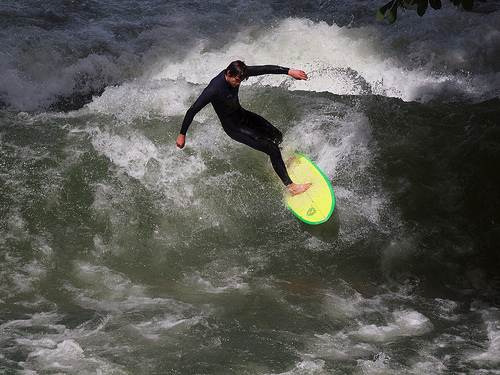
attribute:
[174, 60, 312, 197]
man — balancing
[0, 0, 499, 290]
waves — black, riding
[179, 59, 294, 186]
wet suit — black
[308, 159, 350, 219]
stripe — green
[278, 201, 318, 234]
stripe — green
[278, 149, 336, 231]
board — side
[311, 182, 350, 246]
stripe — green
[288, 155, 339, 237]
board — side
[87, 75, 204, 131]
cap — frothy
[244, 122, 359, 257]
board — side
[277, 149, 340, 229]
board — side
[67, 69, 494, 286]
waves — vicous, crashing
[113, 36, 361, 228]
man — shoeless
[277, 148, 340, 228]
stripe — green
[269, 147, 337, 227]
board — side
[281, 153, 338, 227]
stripe — green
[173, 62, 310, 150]
arms — outstrechted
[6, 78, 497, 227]
waves — foamy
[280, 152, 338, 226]
surfboard — lime, green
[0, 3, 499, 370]
water — dark